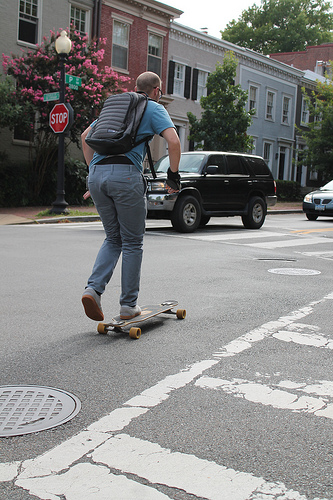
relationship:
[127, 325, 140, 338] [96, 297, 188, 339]
wheel in skateboard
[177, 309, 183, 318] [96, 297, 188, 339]
wheel in skateboard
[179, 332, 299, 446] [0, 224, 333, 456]
cracked line in road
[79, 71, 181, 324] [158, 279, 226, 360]
man in street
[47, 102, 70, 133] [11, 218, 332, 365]
sign in street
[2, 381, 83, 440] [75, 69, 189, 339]
manhole in skateboarder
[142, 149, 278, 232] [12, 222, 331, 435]
car on street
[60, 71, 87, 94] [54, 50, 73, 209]
sign on pole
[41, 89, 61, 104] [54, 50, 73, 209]
sign on pole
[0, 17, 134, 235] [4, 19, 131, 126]
tree with flowers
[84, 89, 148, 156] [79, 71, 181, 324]
backpack on man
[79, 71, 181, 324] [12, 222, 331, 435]
man skateboarding down street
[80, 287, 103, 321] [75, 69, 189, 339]
shoe of skateboarder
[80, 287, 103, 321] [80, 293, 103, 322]
shoe with soles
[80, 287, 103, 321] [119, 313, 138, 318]
shoe with soles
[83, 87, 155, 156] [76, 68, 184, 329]
backpack of person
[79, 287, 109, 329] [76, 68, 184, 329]
shoe of person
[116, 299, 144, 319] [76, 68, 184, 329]
shoe of person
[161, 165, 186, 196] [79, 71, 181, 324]
hand of man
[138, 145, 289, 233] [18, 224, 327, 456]
car placed in road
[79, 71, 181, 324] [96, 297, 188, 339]
man riding skateboard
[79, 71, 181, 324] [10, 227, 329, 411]
man riding down street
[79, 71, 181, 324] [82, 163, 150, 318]
man dressed in blue jeans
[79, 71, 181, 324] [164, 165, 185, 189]
man wearing glove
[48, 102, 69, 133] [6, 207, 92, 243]
sign on corner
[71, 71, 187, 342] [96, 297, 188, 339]
man riding skateboard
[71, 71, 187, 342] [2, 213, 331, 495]
man on street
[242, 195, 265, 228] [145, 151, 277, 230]
tire on truck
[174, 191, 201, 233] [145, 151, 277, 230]
tire on truck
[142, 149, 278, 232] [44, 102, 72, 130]
car at sign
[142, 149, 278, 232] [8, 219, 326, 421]
car on street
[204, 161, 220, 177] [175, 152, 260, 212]
mirror on truck